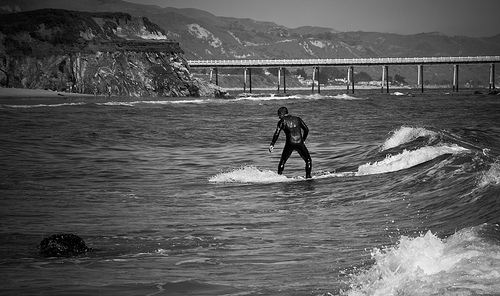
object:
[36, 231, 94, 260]
object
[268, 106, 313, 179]
man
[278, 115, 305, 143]
wet suit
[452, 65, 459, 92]
pillar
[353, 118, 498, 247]
wave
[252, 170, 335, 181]
surfboard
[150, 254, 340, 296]
ripples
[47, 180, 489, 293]
water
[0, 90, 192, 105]
beach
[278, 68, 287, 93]
pillar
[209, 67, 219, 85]
pillar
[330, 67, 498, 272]
waves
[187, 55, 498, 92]
bridge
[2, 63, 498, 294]
water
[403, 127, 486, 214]
wave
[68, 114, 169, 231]
water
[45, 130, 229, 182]
ripples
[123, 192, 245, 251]
ripples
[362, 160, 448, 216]
ripples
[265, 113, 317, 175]
wet suit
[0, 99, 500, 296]
ocean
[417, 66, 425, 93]
pillar